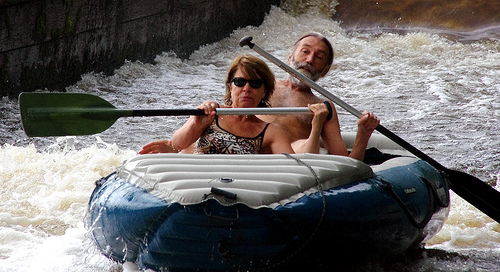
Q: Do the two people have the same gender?
A: No, they are both male and female.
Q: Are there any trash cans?
A: No, there are no trash cans.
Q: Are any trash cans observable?
A: No, there are no trash cans.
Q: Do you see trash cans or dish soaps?
A: No, there are no trash cans or dish soaps.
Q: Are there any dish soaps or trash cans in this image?
A: No, there are no trash cans or dish soaps.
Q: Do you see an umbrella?
A: No, there are no umbrellas.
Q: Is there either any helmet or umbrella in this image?
A: No, there are no umbrellas or helmets.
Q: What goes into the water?
A: The oar goes into the water.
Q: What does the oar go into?
A: The oar goes into the water.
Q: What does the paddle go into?
A: The oar goes into the water.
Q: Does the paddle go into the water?
A: Yes, the paddle goes into the water.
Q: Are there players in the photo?
A: No, there are no players.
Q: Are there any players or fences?
A: No, there are no players or fences.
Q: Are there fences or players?
A: No, there are no players or fences.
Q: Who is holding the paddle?
A: The girl is holding the paddle.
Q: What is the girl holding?
A: The girl is holding the paddle.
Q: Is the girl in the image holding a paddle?
A: Yes, the girl is holding a paddle.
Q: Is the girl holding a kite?
A: No, the girl is holding a paddle.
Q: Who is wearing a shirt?
A: The girl is wearing a shirt.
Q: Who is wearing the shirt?
A: The girl is wearing a shirt.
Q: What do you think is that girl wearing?
A: The girl is wearing a shirt.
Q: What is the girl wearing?
A: The girl is wearing a shirt.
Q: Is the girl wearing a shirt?
A: Yes, the girl is wearing a shirt.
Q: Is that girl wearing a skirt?
A: No, the girl is wearing a shirt.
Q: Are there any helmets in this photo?
A: No, there are no helmets.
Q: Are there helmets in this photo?
A: No, there are no helmets.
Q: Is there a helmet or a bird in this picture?
A: No, there are no helmets or birds.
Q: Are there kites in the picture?
A: No, there are no kites.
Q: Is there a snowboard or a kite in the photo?
A: No, there are no kites or snowboards.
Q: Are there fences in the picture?
A: No, there are no fences.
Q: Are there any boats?
A: Yes, there is a boat.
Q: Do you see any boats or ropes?
A: Yes, there is a boat.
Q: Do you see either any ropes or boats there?
A: Yes, there is a boat.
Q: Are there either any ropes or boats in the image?
A: Yes, there is a boat.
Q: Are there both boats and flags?
A: No, there is a boat but no flags.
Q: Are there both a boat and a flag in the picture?
A: No, there is a boat but no flags.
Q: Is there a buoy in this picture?
A: No, there are no buoys.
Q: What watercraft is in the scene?
A: The watercraft is a boat.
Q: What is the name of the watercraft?
A: The watercraft is a boat.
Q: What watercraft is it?
A: The watercraft is a boat.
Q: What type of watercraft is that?
A: This is a boat.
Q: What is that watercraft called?
A: This is a boat.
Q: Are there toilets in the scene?
A: No, there are no toilets.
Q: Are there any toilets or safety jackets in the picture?
A: No, there are no toilets or safety jackets.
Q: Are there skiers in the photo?
A: No, there are no skiers.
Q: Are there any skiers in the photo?
A: No, there are no skiers.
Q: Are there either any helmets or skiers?
A: No, there are no skiers or helmets.